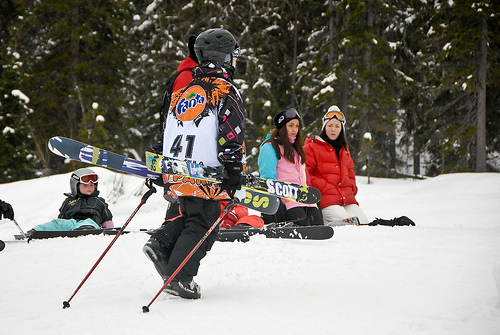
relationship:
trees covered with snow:
[248, 12, 471, 107] [11, 175, 492, 333]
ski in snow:
[211, 217, 338, 249] [26, 184, 475, 320]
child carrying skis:
[146, 30, 246, 302] [44, 130, 280, 211]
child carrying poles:
[146, 30, 246, 302] [53, 180, 243, 314]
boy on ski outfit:
[21, 167, 115, 238] [32, 195, 112, 230]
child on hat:
[305, 105, 370, 225] [318, 104, 345, 136]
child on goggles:
[305, 105, 370, 225] [320, 111, 345, 121]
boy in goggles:
[51, 150, 155, 245] [76, 167, 101, 189]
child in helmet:
[146, 30, 246, 302] [196, 27, 238, 64]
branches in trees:
[1, 44, 499, 176] [1, 0, 498, 180]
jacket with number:
[150, 68, 251, 209] [162, 130, 202, 168]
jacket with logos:
[150, 68, 251, 209] [170, 86, 217, 124]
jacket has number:
[150, 68, 251, 209] [167, 121, 207, 165]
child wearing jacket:
[257, 107, 324, 226] [261, 139, 313, 213]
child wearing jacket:
[257, 107, 324, 226] [252, 147, 303, 178]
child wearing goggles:
[146, 30, 246, 302] [206, 43, 242, 87]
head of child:
[274, 103, 301, 146] [257, 107, 324, 226]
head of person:
[190, 25, 243, 70] [145, 25, 252, 297]